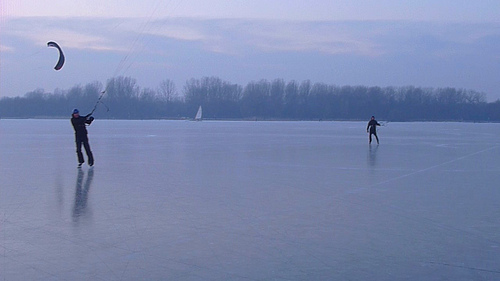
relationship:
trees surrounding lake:
[0, 74, 498, 121] [0, 117, 498, 279]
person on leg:
[361, 112, 392, 153] [80, 141, 102, 170]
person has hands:
[57, 102, 106, 174] [80, 112, 102, 128]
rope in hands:
[85, 21, 165, 118] [80, 112, 102, 128]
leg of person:
[70, 140, 90, 165] [55, 105, 135, 217]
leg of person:
[367, 130, 373, 146] [362, 112, 383, 147]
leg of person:
[373, 132, 380, 144] [366, 115, 384, 145]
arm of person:
[365, 118, 371, 133] [365, 114, 382, 146]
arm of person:
[62, 87, 146, 176] [61, 100, 99, 175]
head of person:
[70, 107, 78, 119] [361, 113, 386, 146]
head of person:
[368, 112, 380, 122] [365, 112, 383, 144]